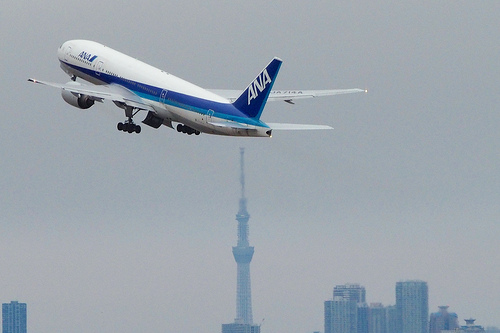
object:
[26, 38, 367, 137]
plane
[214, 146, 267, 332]
tower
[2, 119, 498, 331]
distance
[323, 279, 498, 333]
buildings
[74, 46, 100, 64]
logo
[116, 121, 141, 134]
wheels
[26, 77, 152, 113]
wing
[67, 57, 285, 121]
stripes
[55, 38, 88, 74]
front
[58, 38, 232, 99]
top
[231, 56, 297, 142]
tail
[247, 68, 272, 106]
ana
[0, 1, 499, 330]
sky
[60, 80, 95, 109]
engine